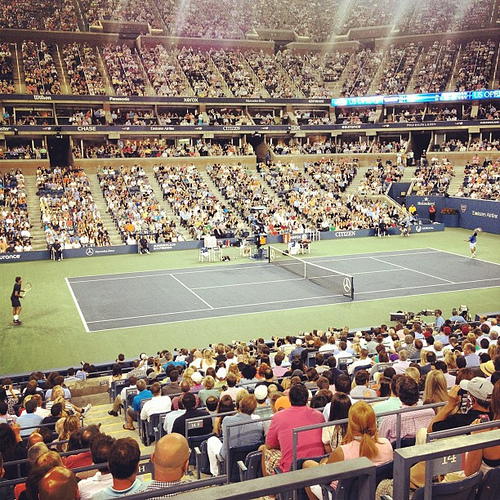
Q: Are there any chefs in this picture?
A: No, there are no chefs.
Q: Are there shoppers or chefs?
A: No, there are no chefs or shoppers.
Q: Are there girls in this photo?
A: No, there are no girls.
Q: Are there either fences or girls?
A: No, there are no girls or fences.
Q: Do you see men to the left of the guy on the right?
A: Yes, there is a man to the left of the guy.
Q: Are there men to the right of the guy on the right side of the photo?
A: No, the man is to the left of the guy.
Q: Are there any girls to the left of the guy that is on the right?
A: No, there is a man to the left of the guy.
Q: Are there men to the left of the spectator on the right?
A: Yes, there is a man to the left of the spectator.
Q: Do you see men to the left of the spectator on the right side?
A: Yes, there is a man to the left of the spectator.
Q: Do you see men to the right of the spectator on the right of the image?
A: No, the man is to the left of the spectator.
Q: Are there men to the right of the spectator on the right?
A: No, the man is to the left of the spectator.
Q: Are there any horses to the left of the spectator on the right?
A: No, there is a man to the left of the spectator.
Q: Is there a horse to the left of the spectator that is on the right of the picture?
A: No, there is a man to the left of the spectator.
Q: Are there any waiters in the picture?
A: No, there are no waiters.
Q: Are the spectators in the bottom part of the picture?
A: Yes, the spectators are in the bottom of the image.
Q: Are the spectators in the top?
A: No, the spectators are in the bottom of the image.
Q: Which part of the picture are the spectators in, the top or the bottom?
A: The spectators are in the bottom of the image.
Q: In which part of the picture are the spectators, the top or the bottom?
A: The spectators are in the bottom of the image.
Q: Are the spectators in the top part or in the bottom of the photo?
A: The spectators are in the bottom of the image.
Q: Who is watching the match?
A: The spectators are watching the match.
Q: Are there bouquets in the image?
A: No, there are no bouquets.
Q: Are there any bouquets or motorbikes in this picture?
A: No, there are no bouquets or motorbikes.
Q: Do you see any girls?
A: No, there are no girls.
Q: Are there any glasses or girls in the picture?
A: No, there are no girls or glasses.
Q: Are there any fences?
A: No, there are no fences.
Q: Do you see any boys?
A: No, there are no boys.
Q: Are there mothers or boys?
A: No, there are no boys or mothers.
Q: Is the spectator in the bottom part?
A: Yes, the spectator is in the bottom of the image.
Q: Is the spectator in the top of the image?
A: No, the spectator is in the bottom of the image.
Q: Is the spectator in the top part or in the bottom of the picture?
A: The spectator is in the bottom of the image.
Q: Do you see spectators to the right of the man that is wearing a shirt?
A: Yes, there is a spectator to the right of the man.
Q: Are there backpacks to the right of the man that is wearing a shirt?
A: No, there is a spectator to the right of the man.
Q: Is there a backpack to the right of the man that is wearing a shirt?
A: No, there is a spectator to the right of the man.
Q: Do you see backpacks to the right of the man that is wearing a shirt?
A: No, there is a spectator to the right of the man.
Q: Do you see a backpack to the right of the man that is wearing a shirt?
A: No, there is a spectator to the right of the man.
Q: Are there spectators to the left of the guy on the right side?
A: Yes, there is a spectator to the left of the guy.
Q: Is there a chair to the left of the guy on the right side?
A: No, there is a spectator to the left of the guy.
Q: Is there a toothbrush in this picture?
A: No, there are no toothbrushes.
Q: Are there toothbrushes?
A: No, there are no toothbrushes.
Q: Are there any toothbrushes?
A: No, there are no toothbrushes.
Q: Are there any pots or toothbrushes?
A: No, there are no toothbrushes or pots.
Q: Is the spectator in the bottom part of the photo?
A: Yes, the spectator is in the bottom of the image.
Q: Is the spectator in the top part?
A: No, the spectator is in the bottom of the image.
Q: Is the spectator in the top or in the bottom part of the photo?
A: The spectator is in the bottom of the image.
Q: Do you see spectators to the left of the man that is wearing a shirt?
A: Yes, there is a spectator to the left of the man.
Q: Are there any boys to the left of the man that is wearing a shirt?
A: No, there is a spectator to the left of the man.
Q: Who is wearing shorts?
A: The player is wearing shorts.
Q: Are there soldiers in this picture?
A: No, there are no soldiers.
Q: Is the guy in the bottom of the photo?
A: Yes, the guy is in the bottom of the image.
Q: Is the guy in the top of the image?
A: No, the guy is in the bottom of the image.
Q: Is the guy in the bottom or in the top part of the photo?
A: The guy is in the bottom of the image.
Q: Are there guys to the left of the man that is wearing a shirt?
A: Yes, there is a guy to the left of the man.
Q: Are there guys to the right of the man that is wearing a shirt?
A: No, the guy is to the left of the man.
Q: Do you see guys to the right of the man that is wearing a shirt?
A: No, the guy is to the left of the man.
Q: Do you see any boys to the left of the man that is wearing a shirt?
A: No, there is a guy to the left of the man.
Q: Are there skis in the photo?
A: No, there are no skis.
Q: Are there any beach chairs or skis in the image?
A: No, there are no skis or beach chairs.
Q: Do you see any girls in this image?
A: No, there are no girls.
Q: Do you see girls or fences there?
A: No, there are no girls or fences.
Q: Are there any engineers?
A: No, there are no engineers.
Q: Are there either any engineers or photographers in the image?
A: No, there are no engineers or photographers.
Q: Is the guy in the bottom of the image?
A: Yes, the guy is in the bottom of the image.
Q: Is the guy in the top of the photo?
A: No, the guy is in the bottom of the image.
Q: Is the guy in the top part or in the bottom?
A: The guy is in the bottom of the image.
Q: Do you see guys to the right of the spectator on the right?
A: Yes, there is a guy to the right of the spectator.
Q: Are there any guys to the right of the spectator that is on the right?
A: Yes, there is a guy to the right of the spectator.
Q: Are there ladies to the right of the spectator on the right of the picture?
A: No, there is a guy to the right of the spectator.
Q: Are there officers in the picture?
A: No, there are no officers.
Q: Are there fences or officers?
A: No, there are no officers or fences.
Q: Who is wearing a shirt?
A: The man is wearing a shirt.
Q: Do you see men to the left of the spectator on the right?
A: Yes, there is a man to the left of the spectator.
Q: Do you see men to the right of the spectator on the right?
A: No, the man is to the left of the spectator.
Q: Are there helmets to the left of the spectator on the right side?
A: No, there is a man to the left of the spectator.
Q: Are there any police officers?
A: No, there are no police officers.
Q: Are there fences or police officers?
A: No, there are no police officers or fences.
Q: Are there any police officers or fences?
A: No, there are no police officers or fences.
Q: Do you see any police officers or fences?
A: No, there are no police officers or fences.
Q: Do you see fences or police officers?
A: No, there are no police officers or fences.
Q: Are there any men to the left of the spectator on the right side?
A: Yes, there is a man to the left of the spectator.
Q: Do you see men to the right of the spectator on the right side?
A: No, the man is to the left of the spectator.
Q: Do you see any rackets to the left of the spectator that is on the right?
A: No, there is a man to the left of the spectator.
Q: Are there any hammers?
A: No, there are no hammers.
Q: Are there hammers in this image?
A: No, there are no hammers.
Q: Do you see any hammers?
A: No, there are no hammers.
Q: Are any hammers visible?
A: No, there are no hammers.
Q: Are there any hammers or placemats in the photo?
A: No, there are no hammers or placemats.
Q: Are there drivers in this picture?
A: No, there are no drivers.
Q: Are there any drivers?
A: No, there are no drivers.